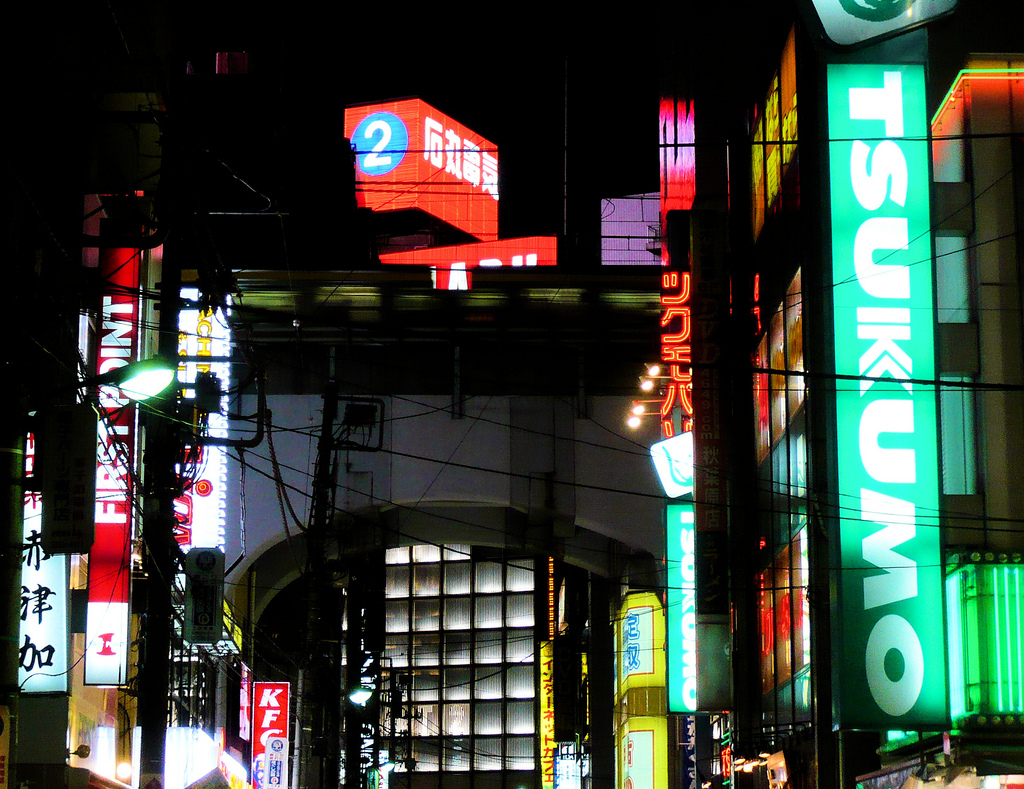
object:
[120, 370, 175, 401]
light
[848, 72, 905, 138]
letter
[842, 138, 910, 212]
letters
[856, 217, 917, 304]
letteru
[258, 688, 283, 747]
kfc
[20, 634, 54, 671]
chineseletters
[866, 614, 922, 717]
lettero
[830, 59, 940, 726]
sign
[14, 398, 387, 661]
wall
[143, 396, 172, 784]
pole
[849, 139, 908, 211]
letter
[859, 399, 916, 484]
letter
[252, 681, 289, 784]
advertisement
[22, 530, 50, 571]
letter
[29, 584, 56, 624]
letter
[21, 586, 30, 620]
letter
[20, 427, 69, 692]
advertisement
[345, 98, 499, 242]
advertisement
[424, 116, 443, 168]
letter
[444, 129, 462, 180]
letter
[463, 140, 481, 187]
letter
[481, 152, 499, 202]
letter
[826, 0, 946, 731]
advertisement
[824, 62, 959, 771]
letters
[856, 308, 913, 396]
letters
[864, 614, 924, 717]
number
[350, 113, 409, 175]
ball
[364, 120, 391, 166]
number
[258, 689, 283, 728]
white text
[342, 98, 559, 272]
building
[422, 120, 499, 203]
white text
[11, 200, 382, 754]
building